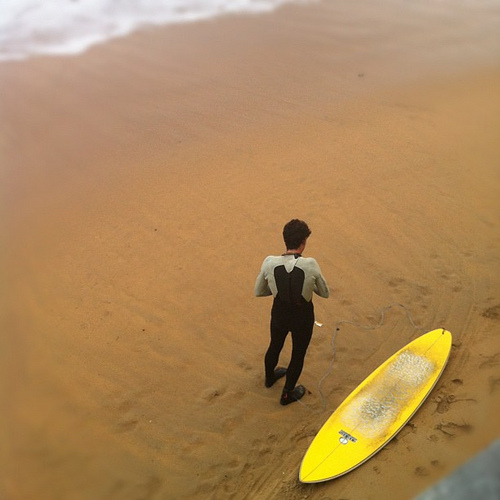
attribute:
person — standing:
[254, 218, 333, 412]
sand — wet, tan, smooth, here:
[1, 1, 500, 498]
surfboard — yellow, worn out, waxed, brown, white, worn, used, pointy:
[298, 327, 453, 484]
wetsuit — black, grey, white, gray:
[253, 254, 330, 407]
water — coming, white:
[0, 0, 281, 61]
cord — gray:
[300, 297, 451, 401]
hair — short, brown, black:
[284, 220, 314, 250]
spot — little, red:
[283, 391, 291, 401]